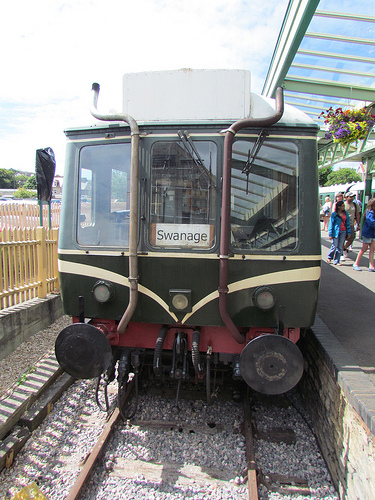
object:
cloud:
[0, 1, 290, 175]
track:
[239, 395, 259, 499]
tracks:
[66, 392, 127, 500]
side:
[75, 412, 124, 500]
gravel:
[149, 433, 191, 460]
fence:
[0, 225, 62, 308]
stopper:
[238, 334, 305, 396]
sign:
[154, 222, 211, 249]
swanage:
[158, 229, 207, 242]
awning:
[258, 0, 374, 105]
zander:
[15, 480, 51, 500]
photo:
[0, 1, 373, 500]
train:
[55, 70, 321, 417]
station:
[0, 0, 375, 500]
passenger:
[326, 197, 350, 267]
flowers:
[319, 100, 373, 149]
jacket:
[326, 210, 350, 239]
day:
[0, 1, 373, 499]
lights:
[93, 282, 111, 303]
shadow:
[111, 369, 351, 493]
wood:
[207, 420, 218, 428]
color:
[128, 324, 152, 343]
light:
[254, 289, 275, 312]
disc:
[55, 322, 110, 380]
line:
[222, 253, 319, 261]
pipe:
[359, 160, 367, 176]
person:
[344, 192, 358, 256]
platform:
[322, 220, 373, 351]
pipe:
[89, 82, 142, 333]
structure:
[318, 132, 372, 174]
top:
[63, 68, 322, 130]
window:
[74, 140, 133, 251]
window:
[137, 138, 219, 256]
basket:
[329, 110, 370, 146]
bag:
[35, 147, 56, 205]